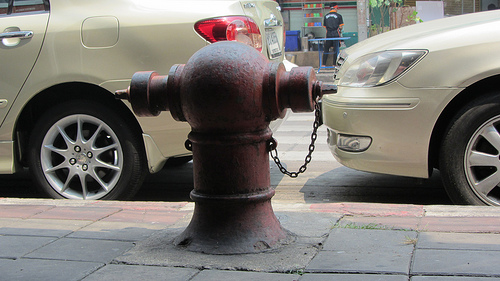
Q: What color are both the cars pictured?
A: Tan.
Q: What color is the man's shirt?
A: Black.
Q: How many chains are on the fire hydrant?
A: 1.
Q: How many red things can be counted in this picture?
A: 9.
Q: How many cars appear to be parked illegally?
A: 2.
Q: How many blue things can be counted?
A: 1.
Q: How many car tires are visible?
A: 2.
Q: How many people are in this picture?
A: 1.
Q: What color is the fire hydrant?
A: Red.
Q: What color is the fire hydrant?
A: Red.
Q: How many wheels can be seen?
A: Two.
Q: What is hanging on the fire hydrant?
A: Chain.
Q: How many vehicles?
A: Two.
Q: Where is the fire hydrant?
A: Sidewalk.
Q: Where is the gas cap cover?
A: Car on the left.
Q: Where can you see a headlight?
A: Car on the right.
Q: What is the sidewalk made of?
A: Brick.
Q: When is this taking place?
A: Daytime.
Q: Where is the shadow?
A: Behind the fire hydrant.